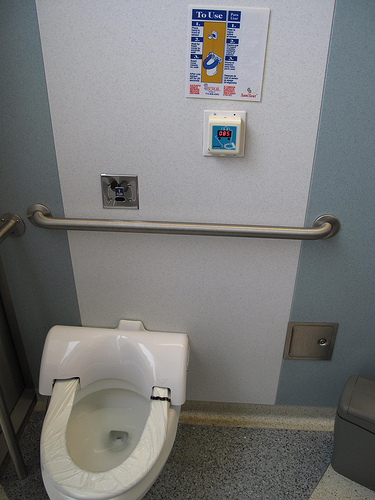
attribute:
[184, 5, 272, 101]
sign — white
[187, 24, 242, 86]
writing — blue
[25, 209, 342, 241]
bar — stainless steel, metal, silver, grab bar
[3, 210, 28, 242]
bar — metal, silver, grab bar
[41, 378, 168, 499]
seat — plastic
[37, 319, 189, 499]
toilet — plastic, white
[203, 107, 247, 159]
thermostat — white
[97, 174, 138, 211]
flush button — metal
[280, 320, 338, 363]
access panel — silver, metal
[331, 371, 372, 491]
trash bin — small, grey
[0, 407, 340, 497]
flooring — speckled, laminate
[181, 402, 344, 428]
baseboard — filthy